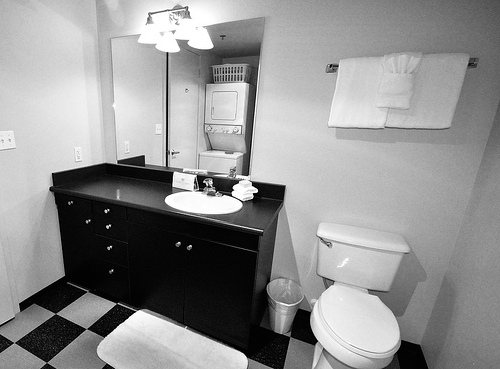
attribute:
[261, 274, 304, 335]
can — white, trash, small, garbage, waste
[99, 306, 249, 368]
rug — white, bath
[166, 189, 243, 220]
sink — white, ceramic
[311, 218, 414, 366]
toilet — white, ceramic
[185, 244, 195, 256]
handle — gray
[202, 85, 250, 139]
dryer — white, reflection, stacked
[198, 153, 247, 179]
washer — white, reflection, stacked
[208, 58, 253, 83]
basket — white, laundry, plastic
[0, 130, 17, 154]
switch — white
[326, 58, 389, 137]
towel — white, hanging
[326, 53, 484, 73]
rack — silver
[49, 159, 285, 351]
vanity — black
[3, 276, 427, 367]
floor — tile, black, white, checkered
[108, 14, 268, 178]
mirror — square, large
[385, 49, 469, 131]
towel — hanging, white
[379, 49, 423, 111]
towel — white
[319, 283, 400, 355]
lid — closed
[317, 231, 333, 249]
handle — silver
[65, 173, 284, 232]
countertop — black